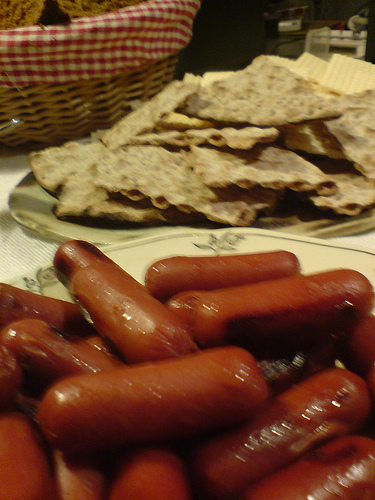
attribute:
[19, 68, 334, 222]
chips — brown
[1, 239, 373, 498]
hot dogs — brown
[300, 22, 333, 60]
chair — white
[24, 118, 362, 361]
plate — silver and white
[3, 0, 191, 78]
cloth — red and white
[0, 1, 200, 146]
basket — tan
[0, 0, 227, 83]
cloth — Red and white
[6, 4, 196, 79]
paper — Red and white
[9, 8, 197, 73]
cloth — red and white